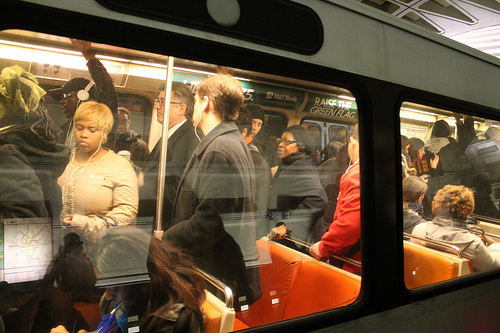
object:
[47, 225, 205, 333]
girl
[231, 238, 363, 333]
seat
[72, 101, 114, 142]
hair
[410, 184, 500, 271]
passenger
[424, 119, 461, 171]
passenger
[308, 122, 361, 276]
passenger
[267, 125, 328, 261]
passenger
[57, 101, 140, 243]
people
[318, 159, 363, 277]
jacket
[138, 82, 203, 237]
man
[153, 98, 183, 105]
glasses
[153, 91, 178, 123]
face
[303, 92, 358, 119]
advertisement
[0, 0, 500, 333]
train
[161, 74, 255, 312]
man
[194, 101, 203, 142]
headphones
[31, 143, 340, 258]
reflection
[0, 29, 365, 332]
window